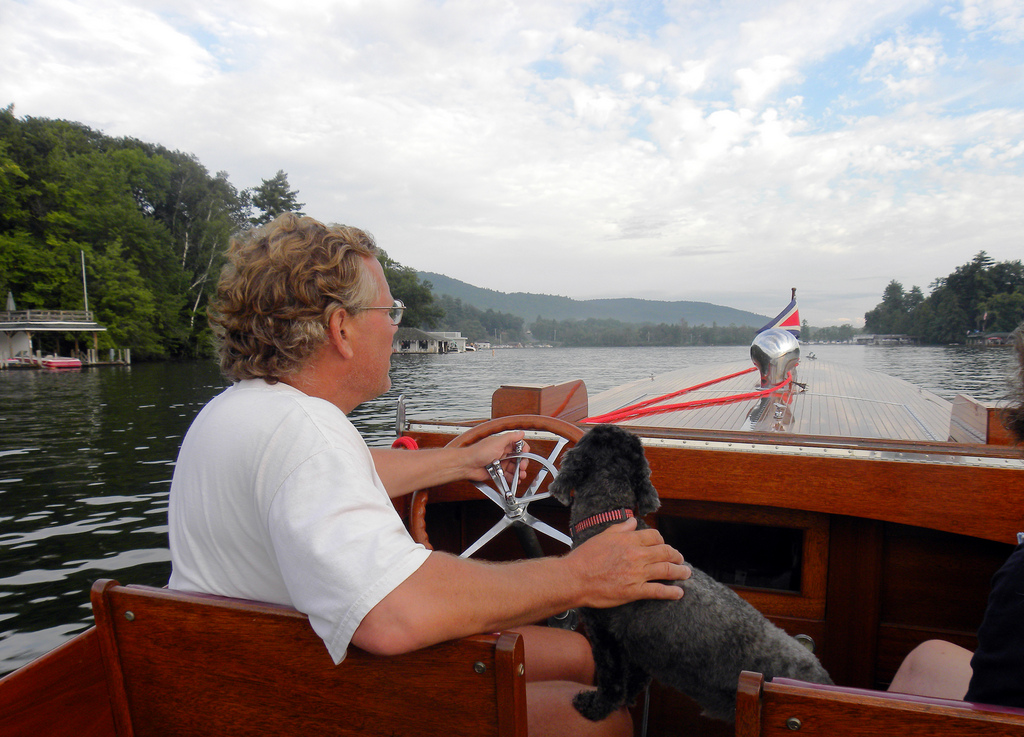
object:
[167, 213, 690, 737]
person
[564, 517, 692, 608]
hand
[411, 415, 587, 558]
wheel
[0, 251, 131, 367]
house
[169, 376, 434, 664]
shirt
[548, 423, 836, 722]
dog